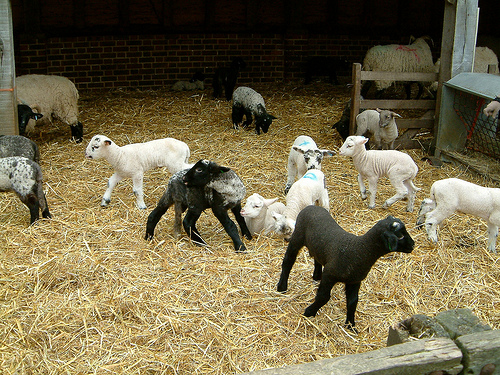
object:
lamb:
[277, 204, 414, 333]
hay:
[2, 234, 165, 373]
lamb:
[231, 87, 278, 136]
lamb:
[85, 134, 196, 210]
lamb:
[285, 135, 338, 193]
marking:
[298, 140, 310, 146]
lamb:
[1, 156, 52, 225]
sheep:
[359, 36, 435, 101]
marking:
[396, 42, 420, 61]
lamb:
[239, 192, 287, 238]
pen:
[3, 85, 499, 371]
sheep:
[145, 160, 255, 254]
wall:
[15, 21, 334, 80]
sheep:
[211, 62, 241, 102]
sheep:
[339, 135, 422, 214]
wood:
[435, 1, 481, 139]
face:
[397, 226, 415, 253]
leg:
[305, 273, 335, 318]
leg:
[277, 238, 304, 292]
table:
[431, 72, 500, 185]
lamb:
[273, 169, 331, 243]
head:
[258, 112, 273, 134]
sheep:
[303, 58, 350, 85]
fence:
[349, 62, 439, 151]